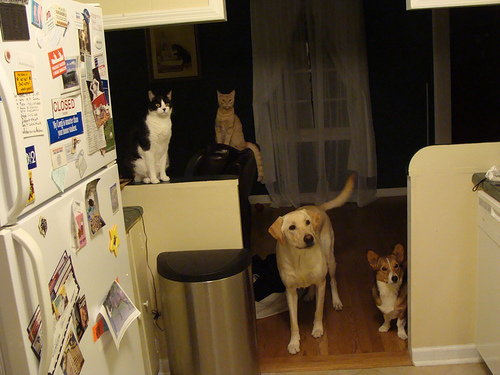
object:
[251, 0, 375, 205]
curtains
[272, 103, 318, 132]
window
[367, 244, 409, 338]
dog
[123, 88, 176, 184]
cat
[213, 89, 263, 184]
cat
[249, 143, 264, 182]
tail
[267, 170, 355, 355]
dog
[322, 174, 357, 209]
tail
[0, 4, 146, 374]
refrigerator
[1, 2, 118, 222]
door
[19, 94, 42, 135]
post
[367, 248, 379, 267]
ear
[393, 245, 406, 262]
ear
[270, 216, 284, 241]
ear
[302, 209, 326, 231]
ear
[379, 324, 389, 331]
paw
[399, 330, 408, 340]
paw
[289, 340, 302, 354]
paw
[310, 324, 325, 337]
paw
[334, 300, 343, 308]
paw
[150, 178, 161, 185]
paw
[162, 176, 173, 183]
paw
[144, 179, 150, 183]
paw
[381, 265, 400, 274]
stare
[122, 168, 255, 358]
counter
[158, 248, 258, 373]
trash can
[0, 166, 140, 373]
door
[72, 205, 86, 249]
object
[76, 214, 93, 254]
object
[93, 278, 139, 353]
object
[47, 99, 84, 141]
object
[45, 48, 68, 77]
object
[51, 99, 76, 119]
sign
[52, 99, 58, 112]
letters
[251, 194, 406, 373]
flooring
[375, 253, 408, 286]
head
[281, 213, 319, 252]
head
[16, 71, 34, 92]
magnet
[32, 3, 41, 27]
magnet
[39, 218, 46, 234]
magnet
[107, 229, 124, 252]
magnet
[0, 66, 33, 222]
handle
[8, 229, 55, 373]
handle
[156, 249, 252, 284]
lid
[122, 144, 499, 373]
kitchen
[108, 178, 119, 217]
paper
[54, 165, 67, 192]
paper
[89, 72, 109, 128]
paper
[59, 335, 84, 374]
paper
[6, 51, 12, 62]
magnet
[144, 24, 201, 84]
picture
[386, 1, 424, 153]
wall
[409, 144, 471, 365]
wall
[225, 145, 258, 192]
chair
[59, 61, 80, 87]
photo